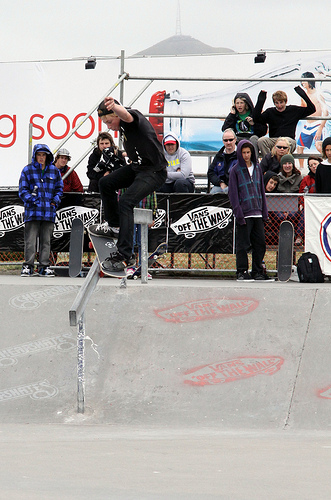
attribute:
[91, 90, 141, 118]
hat — Black, backwards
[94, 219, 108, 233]
laces — white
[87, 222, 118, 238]
tennis shoe — black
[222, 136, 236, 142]
sunglasses — dark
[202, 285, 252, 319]
ramp — Cement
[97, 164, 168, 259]
pants — black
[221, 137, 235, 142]
glasses — sun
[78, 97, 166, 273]
man — skateboarding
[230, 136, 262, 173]
jacket — hooded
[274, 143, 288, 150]
sunglasses — dark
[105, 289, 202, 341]
ramp — cement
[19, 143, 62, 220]
plaid jacket — plaid 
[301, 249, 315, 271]
backpack — black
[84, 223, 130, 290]
skateboard — black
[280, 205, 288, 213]
fence — metal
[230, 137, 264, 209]
jacket — purple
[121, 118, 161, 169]
shirt — black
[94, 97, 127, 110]
hat — black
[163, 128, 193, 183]
sweater — grey